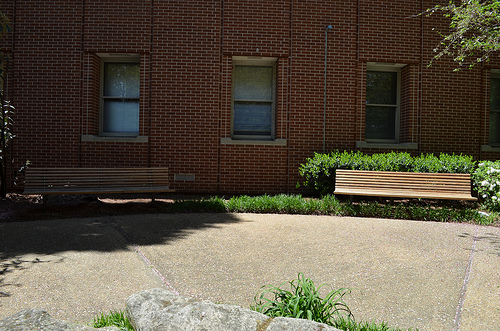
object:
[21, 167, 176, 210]
bench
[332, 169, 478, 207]
bench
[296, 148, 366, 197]
bushes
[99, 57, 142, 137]
window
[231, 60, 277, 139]
window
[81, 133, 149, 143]
window sill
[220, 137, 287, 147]
window sill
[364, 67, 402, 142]
window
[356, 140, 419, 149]
window sill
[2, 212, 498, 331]
walkway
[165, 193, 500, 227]
grass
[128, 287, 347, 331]
rock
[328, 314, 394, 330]
grass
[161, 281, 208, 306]
grass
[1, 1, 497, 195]
building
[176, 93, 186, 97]
brick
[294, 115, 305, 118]
brick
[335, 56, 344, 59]
brick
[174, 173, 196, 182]
vent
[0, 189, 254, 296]
shadow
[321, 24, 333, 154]
conduit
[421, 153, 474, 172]
shrub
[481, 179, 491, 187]
flowers